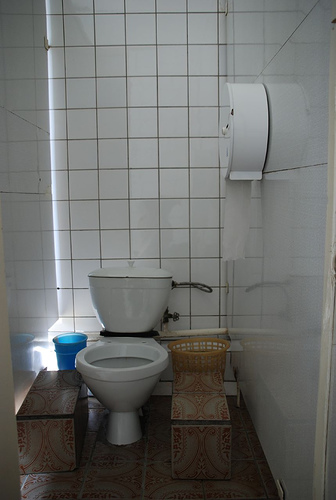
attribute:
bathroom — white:
[3, 2, 332, 499]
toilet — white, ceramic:
[76, 271, 177, 447]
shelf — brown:
[173, 368, 238, 480]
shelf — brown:
[21, 358, 89, 474]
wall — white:
[4, 4, 67, 411]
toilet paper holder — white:
[214, 81, 263, 186]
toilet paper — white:
[215, 184, 251, 269]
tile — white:
[49, 1, 236, 395]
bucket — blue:
[55, 331, 87, 379]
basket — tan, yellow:
[162, 337, 230, 398]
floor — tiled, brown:
[16, 380, 271, 500]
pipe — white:
[161, 298, 188, 330]